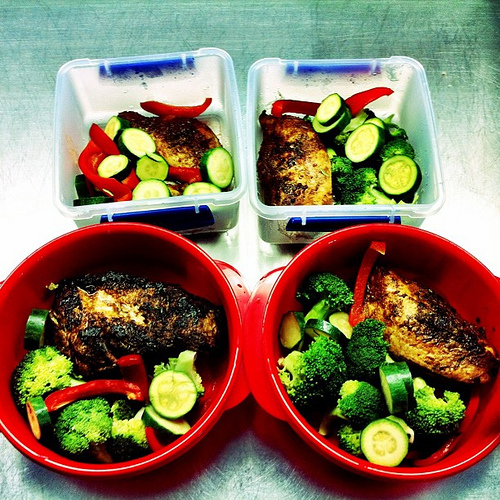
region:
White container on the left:
[50, 48, 245, 244]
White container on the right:
[243, 55, 438, 240]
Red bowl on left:
[0, 220, 252, 476]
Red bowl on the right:
[250, 225, 495, 485]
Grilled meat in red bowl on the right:
[362, 260, 497, 384]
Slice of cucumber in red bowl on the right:
[357, 418, 409, 465]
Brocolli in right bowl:
[276, 268, 466, 449]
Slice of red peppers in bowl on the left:
[31, 378, 141, 413]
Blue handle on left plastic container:
[97, 54, 194, 79]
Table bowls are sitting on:
[2, 3, 497, 496]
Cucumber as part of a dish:
[356, 410, 413, 472]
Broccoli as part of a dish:
[275, 334, 345, 393]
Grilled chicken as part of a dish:
[357, 265, 498, 389]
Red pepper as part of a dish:
[44, 353, 153, 408]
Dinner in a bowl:
[255, 221, 499, 498]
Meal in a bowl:
[0, 224, 246, 479]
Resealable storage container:
[249, 53, 446, 230]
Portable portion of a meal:
[50, 38, 249, 232]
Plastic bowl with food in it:
[242, 217, 498, 482]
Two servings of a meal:
[3, 53, 498, 474]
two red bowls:
[1, 234, 497, 481]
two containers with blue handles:
[40, 45, 448, 224]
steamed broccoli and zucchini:
[292, 342, 416, 474]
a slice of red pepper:
[346, 235, 388, 324]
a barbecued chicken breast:
[375, 267, 499, 375]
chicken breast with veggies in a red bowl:
[22, 267, 217, 449]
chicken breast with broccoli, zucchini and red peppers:
[75, 102, 230, 194]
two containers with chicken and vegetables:
[61, 57, 436, 217]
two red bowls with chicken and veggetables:
[2, 220, 499, 484]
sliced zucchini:
[148, 372, 197, 438]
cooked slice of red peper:
[43, 376, 139, 413]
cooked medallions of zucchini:
[146, 369, 194, 438]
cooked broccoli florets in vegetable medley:
[13, 352, 69, 387]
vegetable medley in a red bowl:
[19, 333, 200, 460]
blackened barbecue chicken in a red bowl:
[53, 267, 215, 353]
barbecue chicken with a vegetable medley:
[15, 269, 208, 457]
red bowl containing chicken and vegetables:
[263, 226, 497, 481]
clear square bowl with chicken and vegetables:
[250, 49, 447, 219]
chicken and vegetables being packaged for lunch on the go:
[46, 44, 454, 226]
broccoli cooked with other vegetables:
[300, 345, 361, 412]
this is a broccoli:
[297, 349, 338, 395]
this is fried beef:
[77, 284, 164, 345]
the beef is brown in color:
[147, 295, 202, 337]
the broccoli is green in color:
[293, 347, 343, 392]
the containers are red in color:
[233, 294, 269, 398]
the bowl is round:
[92, 230, 157, 263]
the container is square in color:
[147, 57, 204, 94]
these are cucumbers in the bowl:
[329, 112, 374, 146]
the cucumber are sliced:
[318, 100, 347, 130]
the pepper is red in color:
[117, 355, 146, 386]